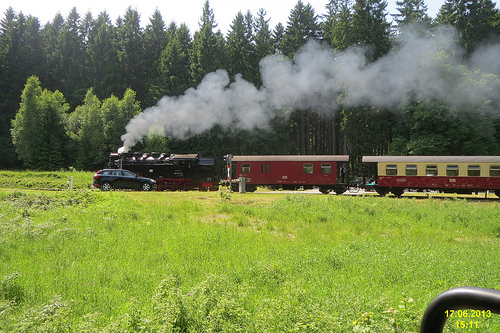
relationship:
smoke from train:
[119, 16, 500, 153] [106, 151, 500, 200]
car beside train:
[92, 165, 158, 190] [106, 151, 500, 200]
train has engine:
[106, 151, 500, 200] [107, 152, 219, 193]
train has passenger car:
[106, 151, 500, 200] [223, 152, 352, 194]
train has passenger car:
[106, 151, 500, 200] [360, 153, 499, 197]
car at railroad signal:
[92, 165, 158, 190] [220, 157, 248, 193]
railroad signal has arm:
[220, 157, 248, 193] [221, 176, 239, 184]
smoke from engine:
[119, 16, 500, 153] [107, 152, 219, 193]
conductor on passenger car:
[338, 162, 349, 184] [223, 152, 352, 194]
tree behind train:
[187, 1, 226, 191] [106, 151, 500, 200]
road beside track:
[35, 186, 500, 204] [0, 182, 496, 200]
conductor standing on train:
[338, 162, 349, 184] [106, 151, 500, 200]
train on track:
[106, 151, 500, 200] [0, 182, 496, 200]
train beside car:
[106, 151, 500, 200] [92, 165, 158, 190]